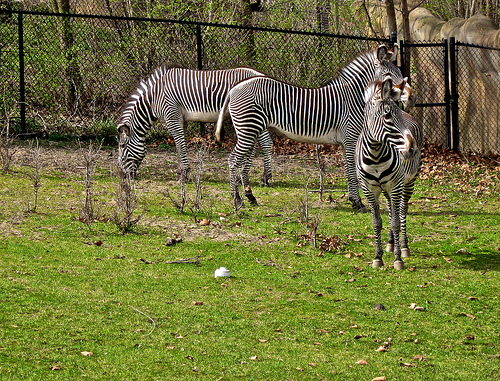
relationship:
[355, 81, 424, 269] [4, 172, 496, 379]
zebra on grass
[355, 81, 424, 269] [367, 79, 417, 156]
zebra has face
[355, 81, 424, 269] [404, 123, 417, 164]
horse has nose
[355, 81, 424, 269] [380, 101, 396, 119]
zebra has eye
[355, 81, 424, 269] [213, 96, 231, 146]
zebra has tail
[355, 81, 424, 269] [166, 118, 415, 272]
zebra has legs